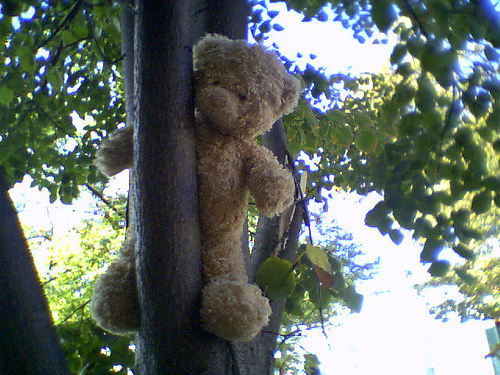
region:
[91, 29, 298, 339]
a brown teddy bear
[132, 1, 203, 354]
a brown tree branch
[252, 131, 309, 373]
a broken tree branch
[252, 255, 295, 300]
a green tree leaf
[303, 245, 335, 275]
a green tree leaf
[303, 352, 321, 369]
a green tree leaf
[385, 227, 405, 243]
a green tree leaf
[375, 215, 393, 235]
a green tree leaf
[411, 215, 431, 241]
a green tree leafa green tree leaf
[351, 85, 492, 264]
leaves of green behind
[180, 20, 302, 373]
a teddy bear in the tree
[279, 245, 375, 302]
a brown leaf surrounded by green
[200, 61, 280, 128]
the black eyes of the bear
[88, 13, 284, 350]
a fuzzy brown bear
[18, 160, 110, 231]
bright sun shine in the back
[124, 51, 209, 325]
a tree trunk holds bear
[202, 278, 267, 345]
fluffy stuffed bear foot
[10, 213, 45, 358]
a piece of trunk on left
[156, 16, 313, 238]
the bear is watching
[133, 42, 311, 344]
A teddy bear in the tree.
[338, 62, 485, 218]
Leaves on the tree.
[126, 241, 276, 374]
Trunk of the tree.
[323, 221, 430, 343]
The sky is very bright.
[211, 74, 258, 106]
The bear eyes are black.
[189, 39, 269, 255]
The teddy bear is brown and fluffy.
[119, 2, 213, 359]
The trunk of the tree is long.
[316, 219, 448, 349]
The sky is clear and blue.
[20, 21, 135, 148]
The leaves are green.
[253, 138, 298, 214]
The teddy bear left arm.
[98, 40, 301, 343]
teddy bear sitting on tree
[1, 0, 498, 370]
tree with green leaves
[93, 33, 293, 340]
cute fluffy teddy bear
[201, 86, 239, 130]
teddy bear nose and mouth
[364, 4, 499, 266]
tree branches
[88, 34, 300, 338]
creepy teddy sitting in tree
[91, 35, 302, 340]
teddy bear watching from a tree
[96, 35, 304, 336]
the teddy bear who can't get down from the tree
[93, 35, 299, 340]
teddy bear getting some shade in the tree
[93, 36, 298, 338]
the teddy bear who won't come down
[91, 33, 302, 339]
Teddy bear stuck in a tree.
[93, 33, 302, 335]
A brown fuzzy bear.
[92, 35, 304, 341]
A brown teddy bear.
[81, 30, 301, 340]
A light brown bear.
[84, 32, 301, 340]
A light brown teddy bear.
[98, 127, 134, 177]
The arm of the teddy bear.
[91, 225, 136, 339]
The leg of the teddy bear.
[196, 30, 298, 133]
The head of the teddy bear.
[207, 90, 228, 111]
The nose of the teddy bear.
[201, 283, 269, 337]
The foot of the teddy bear.